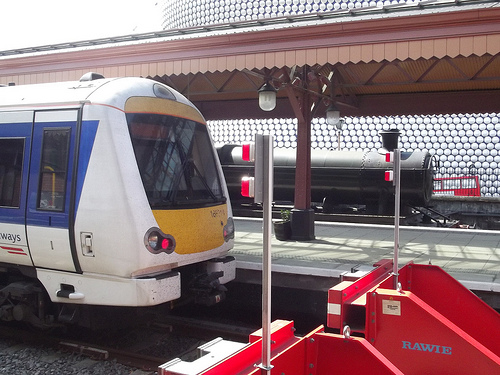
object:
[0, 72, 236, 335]
train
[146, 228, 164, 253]
light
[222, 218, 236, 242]
light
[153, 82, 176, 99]
light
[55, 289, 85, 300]
step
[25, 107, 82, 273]
door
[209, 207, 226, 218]
number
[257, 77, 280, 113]
fixture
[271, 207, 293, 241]
plant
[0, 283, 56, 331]
part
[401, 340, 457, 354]
word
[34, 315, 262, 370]
tracks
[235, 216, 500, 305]
platform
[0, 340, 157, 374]
gravel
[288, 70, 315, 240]
beam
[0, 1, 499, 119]
roof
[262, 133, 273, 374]
pole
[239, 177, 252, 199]
light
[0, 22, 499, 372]
station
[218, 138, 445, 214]
engine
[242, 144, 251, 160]
light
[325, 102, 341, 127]
light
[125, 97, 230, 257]
portion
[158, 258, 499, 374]
stopper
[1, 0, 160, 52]
sky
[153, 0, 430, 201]
building